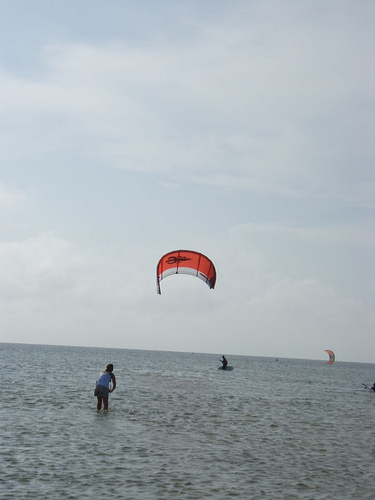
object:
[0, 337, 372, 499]
lake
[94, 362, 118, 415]
woman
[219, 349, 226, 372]
man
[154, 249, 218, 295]
parasail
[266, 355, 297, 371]
person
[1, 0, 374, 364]
sky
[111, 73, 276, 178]
clouds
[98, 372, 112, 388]
top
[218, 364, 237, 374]
board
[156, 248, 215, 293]
kite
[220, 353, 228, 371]
person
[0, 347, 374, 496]
ocean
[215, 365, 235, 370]
surfboard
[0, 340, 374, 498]
ripple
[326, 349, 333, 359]
sail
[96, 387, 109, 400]
shorts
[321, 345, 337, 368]
parasail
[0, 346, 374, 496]
water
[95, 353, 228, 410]
people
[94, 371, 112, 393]
shirt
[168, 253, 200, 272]
design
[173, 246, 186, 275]
rod